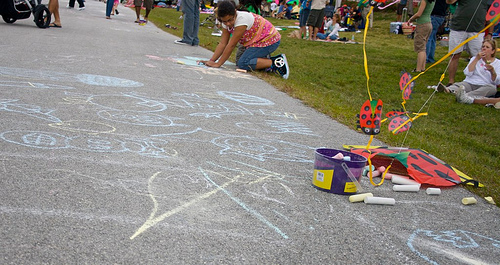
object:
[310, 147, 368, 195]
bucket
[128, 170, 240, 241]
chalk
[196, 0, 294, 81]
girl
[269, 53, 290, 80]
shoes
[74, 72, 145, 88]
drawings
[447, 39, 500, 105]
woman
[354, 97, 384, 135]
kite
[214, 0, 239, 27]
head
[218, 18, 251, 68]
arm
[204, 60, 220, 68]
hand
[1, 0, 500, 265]
pavement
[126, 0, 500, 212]
grass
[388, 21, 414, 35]
cooler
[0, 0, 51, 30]
stroller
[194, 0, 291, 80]
people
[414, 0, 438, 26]
shirt